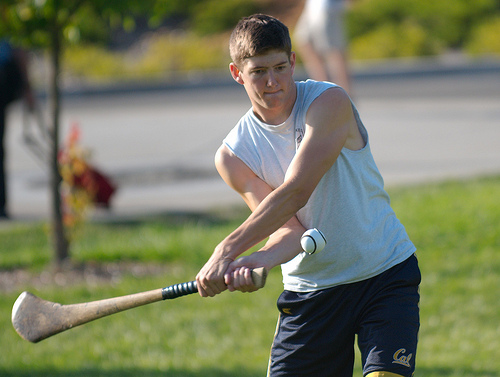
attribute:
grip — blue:
[162, 279, 196, 300]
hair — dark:
[228, 9, 293, 74]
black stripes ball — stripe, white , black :
[298, 225, 329, 257]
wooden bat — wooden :
[2, 261, 279, 347]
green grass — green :
[424, 239, 478, 327]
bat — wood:
[5, 262, 282, 349]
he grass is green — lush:
[413, 196, 475, 295]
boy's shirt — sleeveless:
[203, 88, 374, 191]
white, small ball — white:
[297, 220, 333, 261]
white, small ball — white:
[299, 220, 328, 263]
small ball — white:
[297, 223, 337, 258]